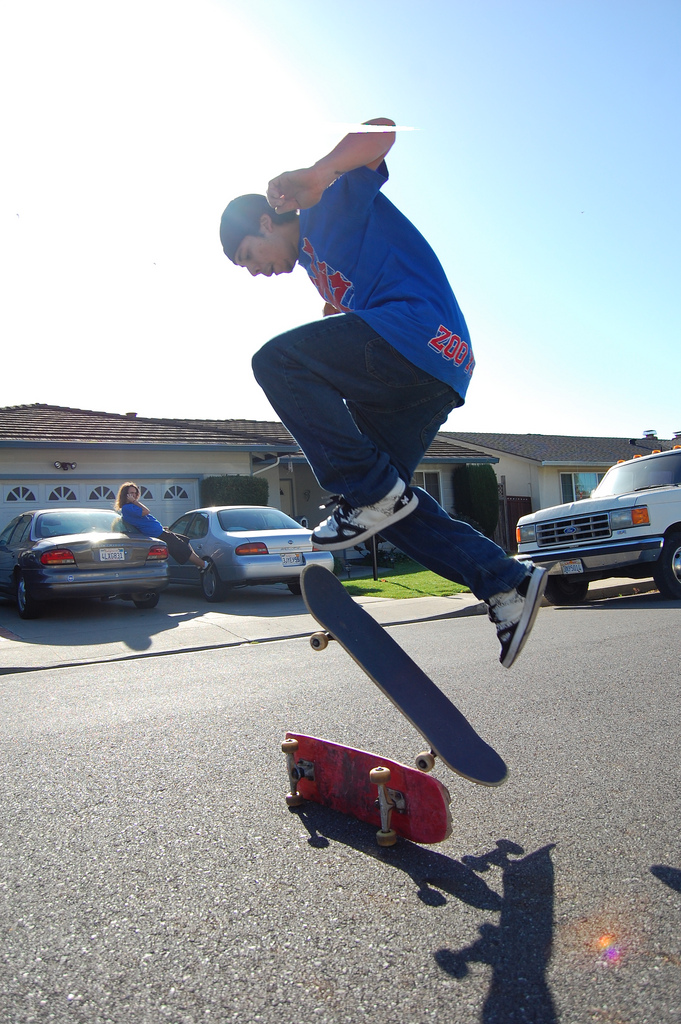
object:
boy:
[220, 117, 548, 668]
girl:
[110, 480, 215, 575]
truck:
[517, 444, 681, 605]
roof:
[0, 402, 300, 451]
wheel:
[415, 751, 435, 771]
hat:
[220, 194, 296, 265]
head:
[220, 194, 298, 277]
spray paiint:
[556, 911, 627, 969]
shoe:
[487, 559, 548, 668]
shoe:
[311, 477, 420, 551]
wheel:
[16, 569, 41, 619]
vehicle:
[0, 507, 171, 620]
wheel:
[201, 558, 225, 604]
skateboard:
[300, 562, 510, 786]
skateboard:
[281, 733, 453, 846]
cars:
[0, 506, 335, 618]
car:
[169, 506, 335, 604]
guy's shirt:
[298, 159, 476, 408]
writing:
[302, 236, 356, 312]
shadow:
[288, 800, 559, 1024]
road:
[0, 589, 681, 1024]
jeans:
[251, 312, 527, 602]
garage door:
[0, 473, 205, 583]